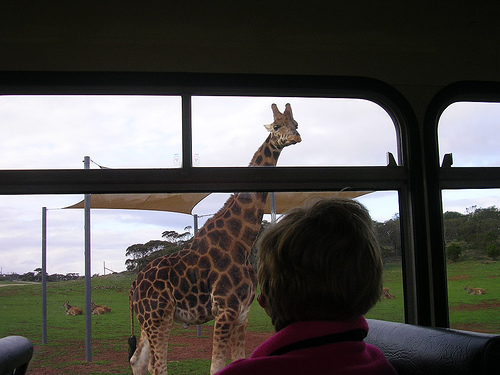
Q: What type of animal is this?
A: A giraffe.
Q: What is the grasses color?
A: Green.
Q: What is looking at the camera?
A: A giraffe.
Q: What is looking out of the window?
A: A person.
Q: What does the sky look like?
A: Cloudy.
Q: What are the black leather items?
A: Seats.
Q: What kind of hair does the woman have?
A: Short blond hair.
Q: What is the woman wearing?
A: A jacket.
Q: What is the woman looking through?
A: A bus window.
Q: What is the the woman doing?
A: Looking through the window.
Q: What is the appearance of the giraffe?
A: The giraffe has stripes.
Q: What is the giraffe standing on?
A: Grass.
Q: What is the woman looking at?
A: A giraffe.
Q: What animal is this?
A: A giraffe.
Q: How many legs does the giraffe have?
A: Four legs.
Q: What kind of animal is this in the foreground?
A: Giraffe.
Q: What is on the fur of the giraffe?
A: Brown and white spots.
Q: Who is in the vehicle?
A: Person in red outer garment.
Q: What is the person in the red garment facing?
A: Giraffe.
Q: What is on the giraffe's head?
A: Ossicones.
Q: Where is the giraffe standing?
A: Green field.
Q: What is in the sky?
A: Clouds.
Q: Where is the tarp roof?
A: Behind the giraffe.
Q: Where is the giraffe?
A: On the ground.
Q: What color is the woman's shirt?
A: Pink.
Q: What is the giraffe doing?
A: Standing.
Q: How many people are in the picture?
A: One.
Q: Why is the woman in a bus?
A: Safety.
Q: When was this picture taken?
A: During the day.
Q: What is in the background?
A: Other animals.